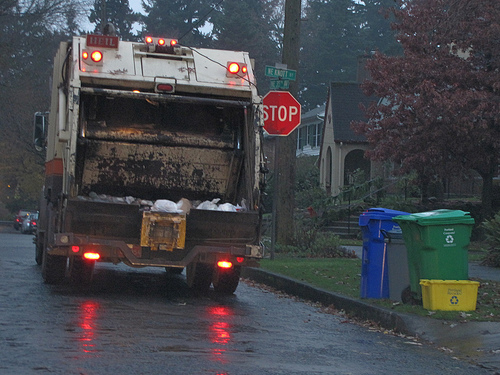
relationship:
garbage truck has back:
[28, 28, 266, 299] [70, 37, 255, 269]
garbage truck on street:
[31, 22, 271, 293] [3, 228, 498, 372]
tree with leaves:
[351, 0, 498, 223] [355, 0, 500, 172]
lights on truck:
[79, 48, 265, 80] [32, 26, 259, 286]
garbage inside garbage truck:
[85, 187, 247, 214] [28, 28, 266, 299]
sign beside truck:
[260, 90, 303, 140] [32, 26, 259, 286]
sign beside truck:
[262, 90, 302, 136] [32, 26, 259, 286]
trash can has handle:
[384, 223, 417, 309] [378, 226, 395, 243]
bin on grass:
[391, 208, 475, 304] [251, 249, 497, 323]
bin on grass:
[358, 207, 413, 299] [251, 249, 497, 323]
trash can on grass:
[380, 225, 411, 303] [251, 249, 497, 323]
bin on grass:
[419, 278, 481, 311] [251, 249, 497, 323]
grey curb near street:
[236, 261, 454, 372] [3, 228, 498, 372]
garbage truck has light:
[31, 22, 271, 293] [206, 253, 240, 269]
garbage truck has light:
[31, 22, 271, 293] [64, 241, 103, 262]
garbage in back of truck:
[78, 191, 248, 215] [30, 35, 266, 304]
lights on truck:
[82, 50, 248, 74] [32, 26, 259, 286]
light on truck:
[82, 251, 99, 263] [32, 26, 259, 286]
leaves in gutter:
[239, 255, 424, 346] [286, 286, 386, 357]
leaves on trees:
[400, 50, 497, 172] [355, 0, 499, 250]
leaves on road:
[239, 255, 424, 354] [0, 221, 489, 373]